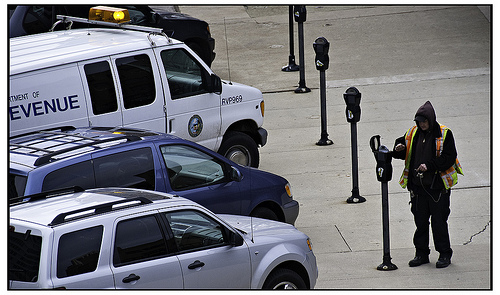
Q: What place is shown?
A: It is a sidewalk.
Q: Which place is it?
A: It is a sidewalk.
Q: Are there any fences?
A: No, there are no fences.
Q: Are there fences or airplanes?
A: No, there are no fences or airplanes.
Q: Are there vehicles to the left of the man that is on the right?
A: Yes, there is a vehicle to the left of the man.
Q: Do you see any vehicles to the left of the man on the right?
A: Yes, there is a vehicle to the left of the man.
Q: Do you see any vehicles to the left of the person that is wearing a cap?
A: Yes, there is a vehicle to the left of the man.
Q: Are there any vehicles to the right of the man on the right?
A: No, the vehicle is to the left of the man.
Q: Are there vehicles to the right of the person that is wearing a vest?
A: No, the vehicle is to the left of the man.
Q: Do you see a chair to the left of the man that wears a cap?
A: No, there is a vehicle to the left of the man.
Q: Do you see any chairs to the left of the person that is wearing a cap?
A: No, there is a vehicle to the left of the man.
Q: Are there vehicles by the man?
A: Yes, there is a vehicle by the man.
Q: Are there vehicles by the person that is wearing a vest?
A: Yes, there is a vehicle by the man.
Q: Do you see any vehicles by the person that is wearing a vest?
A: Yes, there is a vehicle by the man.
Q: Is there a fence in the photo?
A: No, there are no fences.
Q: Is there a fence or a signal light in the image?
A: No, there are no fences or traffic lights.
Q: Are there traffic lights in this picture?
A: No, there are no traffic lights.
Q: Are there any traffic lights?
A: No, there are no traffic lights.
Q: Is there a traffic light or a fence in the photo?
A: No, there are no traffic lights or fences.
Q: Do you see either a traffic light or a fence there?
A: No, there are no traffic lights or fences.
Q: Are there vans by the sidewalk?
A: Yes, there is a van by the sidewalk.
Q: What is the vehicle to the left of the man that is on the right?
A: The vehicle is a van.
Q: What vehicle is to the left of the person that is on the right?
A: The vehicle is a van.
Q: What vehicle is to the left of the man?
A: The vehicle is a van.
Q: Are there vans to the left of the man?
A: Yes, there is a van to the left of the man.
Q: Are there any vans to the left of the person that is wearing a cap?
A: Yes, there is a van to the left of the man.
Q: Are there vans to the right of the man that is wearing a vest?
A: No, the van is to the left of the man.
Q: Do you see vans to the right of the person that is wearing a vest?
A: No, the van is to the left of the man.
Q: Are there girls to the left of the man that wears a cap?
A: No, there is a van to the left of the man.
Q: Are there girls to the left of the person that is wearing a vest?
A: No, there is a van to the left of the man.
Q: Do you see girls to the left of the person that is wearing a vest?
A: No, there is a van to the left of the man.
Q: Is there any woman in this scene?
A: No, there are no women.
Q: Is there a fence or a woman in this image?
A: No, there are no women or fences.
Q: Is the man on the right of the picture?
A: Yes, the man is on the right of the image.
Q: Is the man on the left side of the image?
A: No, the man is on the right of the image.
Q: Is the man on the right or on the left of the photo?
A: The man is on the right of the image.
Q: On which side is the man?
A: The man is on the right of the image.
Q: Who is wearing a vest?
A: The man is wearing a vest.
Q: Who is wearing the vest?
A: The man is wearing a vest.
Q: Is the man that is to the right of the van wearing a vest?
A: Yes, the man is wearing a vest.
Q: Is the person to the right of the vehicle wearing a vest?
A: Yes, the man is wearing a vest.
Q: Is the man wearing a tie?
A: No, the man is wearing a vest.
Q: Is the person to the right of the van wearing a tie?
A: No, the man is wearing a vest.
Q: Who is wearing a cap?
A: The man is wearing a cap.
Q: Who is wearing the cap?
A: The man is wearing a cap.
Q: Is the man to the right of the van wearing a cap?
A: Yes, the man is wearing a cap.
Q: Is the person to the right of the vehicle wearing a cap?
A: Yes, the man is wearing a cap.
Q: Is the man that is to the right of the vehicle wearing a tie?
A: No, the man is wearing a cap.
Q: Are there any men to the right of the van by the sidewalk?
A: Yes, there is a man to the right of the van.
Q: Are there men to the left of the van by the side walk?
A: No, the man is to the right of the van.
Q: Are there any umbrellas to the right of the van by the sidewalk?
A: No, there is a man to the right of the van.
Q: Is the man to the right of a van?
A: Yes, the man is to the right of a van.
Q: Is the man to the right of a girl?
A: No, the man is to the right of a van.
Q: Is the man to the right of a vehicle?
A: Yes, the man is to the right of a vehicle.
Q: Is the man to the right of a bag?
A: No, the man is to the right of a vehicle.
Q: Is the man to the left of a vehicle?
A: No, the man is to the right of a vehicle.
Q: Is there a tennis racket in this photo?
A: No, there are no rackets.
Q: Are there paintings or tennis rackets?
A: No, there are no tennis rackets or paintings.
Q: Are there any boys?
A: No, there are no boys.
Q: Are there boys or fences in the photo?
A: No, there are no boys or fences.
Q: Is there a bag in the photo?
A: No, there are no bags.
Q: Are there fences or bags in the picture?
A: No, there are no bags or fences.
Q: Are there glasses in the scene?
A: No, there are no glasses.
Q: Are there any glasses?
A: No, there are no glasses.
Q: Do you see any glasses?
A: No, there are no glasses.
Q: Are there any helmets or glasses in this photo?
A: No, there are no glasses or helmets.